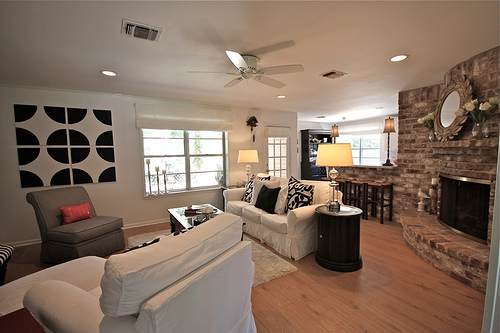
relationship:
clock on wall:
[247, 116, 261, 131] [229, 111, 269, 188]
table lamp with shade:
[380, 116, 397, 166] [382, 113, 398, 133]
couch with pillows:
[223, 172, 343, 262] [243, 173, 323, 221]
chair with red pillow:
[26, 185, 125, 263] [53, 197, 95, 220]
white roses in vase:
[454, 92, 497, 117] [470, 121, 490, 139]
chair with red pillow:
[22, 177, 134, 259] [57, 193, 94, 223]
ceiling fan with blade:
[188, 47, 306, 93] [225, 45, 247, 72]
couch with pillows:
[223, 172, 343, 262] [243, 168, 305, 210]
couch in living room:
[220, 172, 346, 264] [4, 3, 494, 328]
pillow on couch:
[284, 171, 314, 218] [219, 163, 341, 262]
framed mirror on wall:
[413, 79, 486, 143] [392, 47, 480, 242]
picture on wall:
[12, 100, 122, 189] [1, 82, 401, 260]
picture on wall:
[13, 104, 117, 189] [1, 85, 301, 243]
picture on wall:
[12, 100, 122, 189] [11, 87, 151, 244]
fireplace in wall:
[429, 162, 492, 252] [389, 43, 481, 290]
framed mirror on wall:
[432, 70, 473, 142] [403, 124, 432, 174]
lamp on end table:
[311, 140, 357, 211] [317, 201, 368, 271]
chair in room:
[26, 185, 125, 263] [7, 12, 499, 326]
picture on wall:
[12, 100, 122, 189] [2, 42, 499, 296]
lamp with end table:
[316, 143, 354, 212] [314, 203, 365, 273]